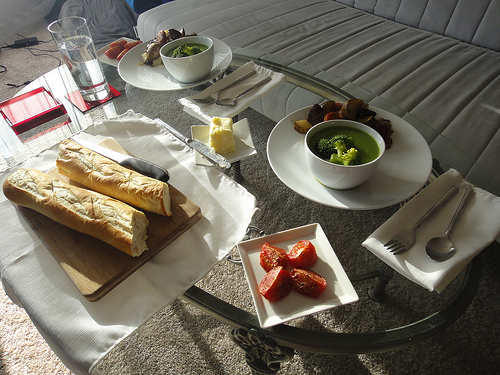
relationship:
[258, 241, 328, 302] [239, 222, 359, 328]
tomatoes on plate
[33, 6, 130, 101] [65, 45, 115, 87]
glass of water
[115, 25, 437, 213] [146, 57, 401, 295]
plates on table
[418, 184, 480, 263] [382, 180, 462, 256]
spoon and fork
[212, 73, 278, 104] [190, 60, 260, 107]
spoon and fork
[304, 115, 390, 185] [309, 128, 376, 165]
bowl of broccoli soup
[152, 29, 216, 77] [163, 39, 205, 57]
bowl of broccoli soup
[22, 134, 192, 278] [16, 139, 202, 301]
bread on cutting board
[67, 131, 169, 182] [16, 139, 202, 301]
knife on cutting board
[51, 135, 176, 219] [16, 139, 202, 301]
bread on cutting board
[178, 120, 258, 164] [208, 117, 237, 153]
plate of butter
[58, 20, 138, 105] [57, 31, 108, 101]
cup of water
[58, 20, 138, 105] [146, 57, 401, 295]
cup on table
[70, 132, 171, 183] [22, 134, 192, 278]
black knife for bread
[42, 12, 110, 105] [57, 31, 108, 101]
glass of water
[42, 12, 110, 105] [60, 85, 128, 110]
glass on coaster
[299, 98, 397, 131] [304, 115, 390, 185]
pile beside bowl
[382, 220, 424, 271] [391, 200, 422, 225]
fork on napkin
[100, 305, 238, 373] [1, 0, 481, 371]
carpet on floor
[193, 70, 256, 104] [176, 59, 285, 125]
silverware on napkin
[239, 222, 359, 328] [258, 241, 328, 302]
plate of tomatoes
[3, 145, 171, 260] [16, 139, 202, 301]
bread on cutting board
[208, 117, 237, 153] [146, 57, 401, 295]
butter on a table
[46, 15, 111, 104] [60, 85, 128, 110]
glass on a coaster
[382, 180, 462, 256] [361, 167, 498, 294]
fork on napkin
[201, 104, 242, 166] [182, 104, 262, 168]
butter on small dish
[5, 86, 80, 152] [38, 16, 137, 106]
red coaster under cup